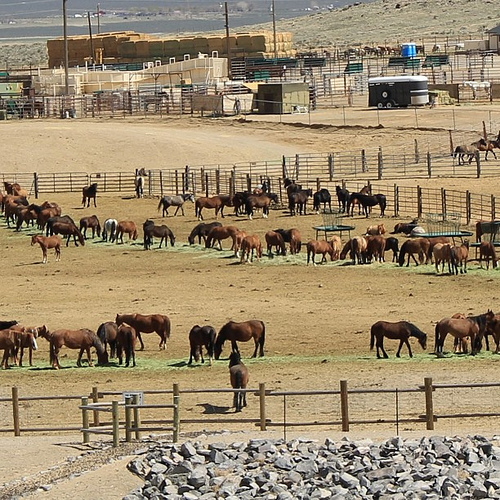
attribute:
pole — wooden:
[10, 386, 19, 436]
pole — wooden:
[172, 382, 179, 442]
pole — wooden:
[258, 383, 265, 430]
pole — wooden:
[339, 379, 349, 430]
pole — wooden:
[423, 377, 433, 431]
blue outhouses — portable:
[396, 40, 421, 59]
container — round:
[366, 66, 432, 118]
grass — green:
[1, 361, 499, 378]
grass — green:
[4, 211, 498, 278]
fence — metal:
[145, 166, 499, 228]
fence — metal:
[175, 149, 498, 194]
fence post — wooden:
[422, 372, 436, 432]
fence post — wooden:
[341, 376, 353, 431]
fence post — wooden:
[255, 381, 267, 429]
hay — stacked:
[232, 24, 323, 74]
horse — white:
[99, 219, 113, 242]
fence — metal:
[1, 377, 499, 447]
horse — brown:
[353, 308, 419, 356]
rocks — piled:
[124, 432, 499, 496]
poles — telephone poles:
[58, 0, 70, 88]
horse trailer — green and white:
[364, 68, 436, 109]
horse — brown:
[373, 307, 421, 359]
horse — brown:
[306, 233, 375, 295]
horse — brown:
[351, 190, 389, 218]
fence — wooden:
[3, 378, 482, 457]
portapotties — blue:
[402, 42, 415, 54]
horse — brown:
[200, 272, 287, 364]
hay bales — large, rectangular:
[36, 12, 304, 90]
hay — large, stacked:
[80, 31, 283, 58]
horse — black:
[203, 303, 278, 365]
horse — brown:
[212, 318, 266, 361]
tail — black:
[107, 220, 117, 241]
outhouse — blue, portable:
[401, 40, 412, 58]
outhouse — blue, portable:
[409, 42, 417, 61]